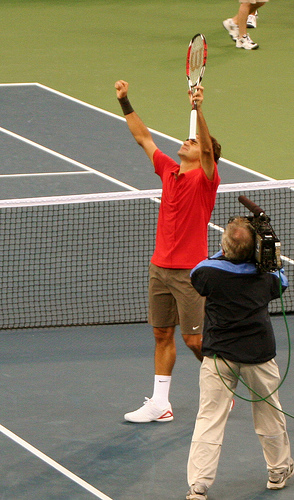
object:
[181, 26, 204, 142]
tennis racket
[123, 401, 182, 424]
shoe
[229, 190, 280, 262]
video camera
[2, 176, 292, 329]
net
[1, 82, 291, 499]
tennis pitch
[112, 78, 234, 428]
man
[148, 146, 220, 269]
shirt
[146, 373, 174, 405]
sock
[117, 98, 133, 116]
wrist band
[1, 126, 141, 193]
line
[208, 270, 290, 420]
wire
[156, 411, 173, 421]
design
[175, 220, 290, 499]
camera man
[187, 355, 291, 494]
pants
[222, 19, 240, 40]
sneaker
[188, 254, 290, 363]
shirt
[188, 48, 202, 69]
w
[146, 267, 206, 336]
shorts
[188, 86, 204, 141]
handle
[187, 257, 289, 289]
stripe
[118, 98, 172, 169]
arm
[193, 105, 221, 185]
arm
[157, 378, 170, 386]
logo